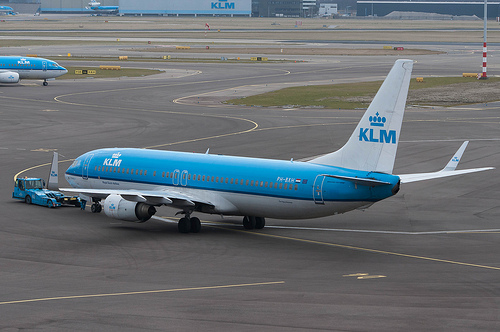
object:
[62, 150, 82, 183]
nose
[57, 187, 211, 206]
wing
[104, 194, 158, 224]
turbine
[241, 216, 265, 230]
wheel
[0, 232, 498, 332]
runway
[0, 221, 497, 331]
tarmac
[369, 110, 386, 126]
logo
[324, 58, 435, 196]
tail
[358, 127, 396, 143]
letters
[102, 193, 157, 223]
engine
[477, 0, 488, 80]
pole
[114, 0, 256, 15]
sign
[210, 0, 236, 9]
letters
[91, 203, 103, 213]
wheels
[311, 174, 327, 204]
door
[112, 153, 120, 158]
logo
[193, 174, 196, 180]
window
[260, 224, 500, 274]
line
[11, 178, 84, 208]
car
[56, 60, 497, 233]
plane